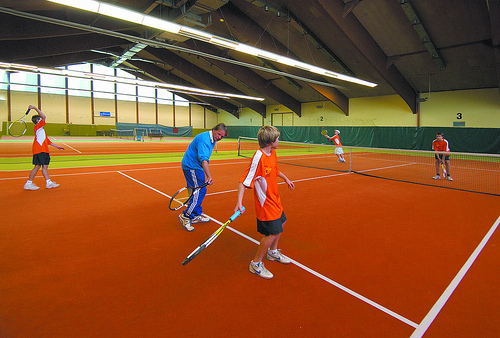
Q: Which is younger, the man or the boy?
A: The boy is younger than the man.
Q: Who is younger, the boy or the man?
A: The boy is younger than the man.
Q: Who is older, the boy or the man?
A: The man is older than the boy.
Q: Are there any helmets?
A: No, there are no helmets.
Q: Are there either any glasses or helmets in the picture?
A: No, there are no helmets or glasses.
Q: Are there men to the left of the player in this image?
A: Yes, there is a man to the left of the player.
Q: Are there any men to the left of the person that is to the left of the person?
A: Yes, there is a man to the left of the player.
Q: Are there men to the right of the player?
A: No, the man is to the left of the player.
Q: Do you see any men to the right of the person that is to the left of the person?
A: No, the man is to the left of the player.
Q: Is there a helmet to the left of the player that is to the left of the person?
A: No, there is a man to the left of the player.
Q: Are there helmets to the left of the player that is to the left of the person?
A: No, there is a man to the left of the player.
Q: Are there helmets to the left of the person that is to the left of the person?
A: No, there is a man to the left of the player.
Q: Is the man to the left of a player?
A: Yes, the man is to the left of a player.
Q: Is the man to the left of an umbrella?
A: No, the man is to the left of a player.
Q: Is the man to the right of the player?
A: No, the man is to the left of the player.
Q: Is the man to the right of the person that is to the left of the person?
A: No, the man is to the left of the player.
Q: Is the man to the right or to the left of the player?
A: The man is to the left of the player.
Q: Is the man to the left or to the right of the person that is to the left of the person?
A: The man is to the left of the player.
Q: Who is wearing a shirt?
A: The man is wearing a shirt.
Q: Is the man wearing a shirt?
A: Yes, the man is wearing a shirt.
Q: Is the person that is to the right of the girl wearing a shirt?
A: Yes, the man is wearing a shirt.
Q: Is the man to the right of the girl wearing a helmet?
A: No, the man is wearing a shirt.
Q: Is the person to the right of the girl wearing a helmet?
A: No, the man is wearing a shirt.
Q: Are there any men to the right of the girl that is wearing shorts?
A: Yes, there is a man to the right of the girl.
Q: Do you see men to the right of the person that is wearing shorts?
A: Yes, there is a man to the right of the girl.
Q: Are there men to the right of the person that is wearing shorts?
A: Yes, there is a man to the right of the girl.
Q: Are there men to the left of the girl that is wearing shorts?
A: No, the man is to the right of the girl.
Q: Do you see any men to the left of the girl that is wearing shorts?
A: No, the man is to the right of the girl.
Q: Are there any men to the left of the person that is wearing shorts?
A: No, the man is to the right of the girl.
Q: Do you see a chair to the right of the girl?
A: No, there is a man to the right of the girl.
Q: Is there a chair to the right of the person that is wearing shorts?
A: No, there is a man to the right of the girl.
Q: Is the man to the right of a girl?
A: Yes, the man is to the right of a girl.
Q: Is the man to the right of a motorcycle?
A: No, the man is to the right of a girl.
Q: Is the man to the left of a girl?
A: No, the man is to the right of a girl.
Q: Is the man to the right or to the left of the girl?
A: The man is to the right of the girl.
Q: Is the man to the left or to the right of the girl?
A: The man is to the right of the girl.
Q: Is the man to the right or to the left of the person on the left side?
A: The man is to the right of the girl.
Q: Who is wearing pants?
A: The man is wearing pants.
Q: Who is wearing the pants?
A: The man is wearing pants.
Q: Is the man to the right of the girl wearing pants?
A: Yes, the man is wearing pants.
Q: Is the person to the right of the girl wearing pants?
A: Yes, the man is wearing pants.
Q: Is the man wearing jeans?
A: No, the man is wearing pants.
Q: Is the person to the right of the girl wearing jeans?
A: No, the man is wearing pants.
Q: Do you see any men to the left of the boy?
A: Yes, there is a man to the left of the boy.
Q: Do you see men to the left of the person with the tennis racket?
A: Yes, there is a man to the left of the boy.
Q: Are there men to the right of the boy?
A: No, the man is to the left of the boy.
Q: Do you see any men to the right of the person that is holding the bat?
A: No, the man is to the left of the boy.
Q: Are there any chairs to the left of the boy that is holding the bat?
A: No, there is a man to the left of the boy.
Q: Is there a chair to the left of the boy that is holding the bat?
A: No, there is a man to the left of the boy.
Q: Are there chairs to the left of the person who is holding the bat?
A: No, there is a man to the left of the boy.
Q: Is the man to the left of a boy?
A: Yes, the man is to the left of a boy.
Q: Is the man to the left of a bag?
A: No, the man is to the left of a boy.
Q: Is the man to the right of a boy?
A: No, the man is to the left of a boy.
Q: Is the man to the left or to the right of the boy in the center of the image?
A: The man is to the left of the boy.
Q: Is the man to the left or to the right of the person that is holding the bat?
A: The man is to the left of the boy.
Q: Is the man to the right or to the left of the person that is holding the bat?
A: The man is to the left of the boy.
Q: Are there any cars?
A: No, there are no cars.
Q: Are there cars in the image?
A: No, there are no cars.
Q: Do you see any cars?
A: No, there are no cars.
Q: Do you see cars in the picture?
A: No, there are no cars.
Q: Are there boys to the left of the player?
A: Yes, there is a boy to the left of the player.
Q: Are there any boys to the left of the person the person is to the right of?
A: Yes, there is a boy to the left of the player.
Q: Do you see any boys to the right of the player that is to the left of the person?
A: No, the boy is to the left of the player.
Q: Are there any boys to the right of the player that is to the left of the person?
A: No, the boy is to the left of the player.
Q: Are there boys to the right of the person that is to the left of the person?
A: No, the boy is to the left of the player.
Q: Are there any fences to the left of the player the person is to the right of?
A: No, there is a boy to the left of the player.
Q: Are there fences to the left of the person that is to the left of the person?
A: No, there is a boy to the left of the player.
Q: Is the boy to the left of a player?
A: Yes, the boy is to the left of a player.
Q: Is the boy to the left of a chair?
A: No, the boy is to the left of a player.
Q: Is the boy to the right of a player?
A: No, the boy is to the left of a player.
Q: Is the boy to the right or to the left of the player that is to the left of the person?
A: The boy is to the left of the player.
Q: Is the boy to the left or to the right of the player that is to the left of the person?
A: The boy is to the left of the player.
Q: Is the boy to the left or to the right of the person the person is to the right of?
A: The boy is to the left of the player.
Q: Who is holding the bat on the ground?
A: The boy is holding the bat.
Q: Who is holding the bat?
A: The boy is holding the bat.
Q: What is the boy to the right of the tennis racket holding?
A: The boy is holding the bat.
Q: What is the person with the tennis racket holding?
A: The boy is holding the bat.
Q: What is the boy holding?
A: The boy is holding the bat.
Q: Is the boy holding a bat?
A: Yes, the boy is holding a bat.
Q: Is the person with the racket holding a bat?
A: Yes, the boy is holding a bat.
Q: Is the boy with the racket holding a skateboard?
A: No, the boy is holding a bat.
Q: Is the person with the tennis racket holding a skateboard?
A: No, the boy is holding a bat.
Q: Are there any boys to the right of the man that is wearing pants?
A: Yes, there is a boy to the right of the man.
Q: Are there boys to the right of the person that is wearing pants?
A: Yes, there is a boy to the right of the man.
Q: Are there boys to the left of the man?
A: No, the boy is to the right of the man.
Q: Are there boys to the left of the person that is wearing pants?
A: No, the boy is to the right of the man.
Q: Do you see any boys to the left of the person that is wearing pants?
A: No, the boy is to the right of the man.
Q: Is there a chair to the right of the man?
A: No, there is a boy to the right of the man.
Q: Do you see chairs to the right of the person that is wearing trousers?
A: No, there is a boy to the right of the man.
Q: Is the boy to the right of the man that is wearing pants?
A: Yes, the boy is to the right of the man.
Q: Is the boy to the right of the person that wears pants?
A: Yes, the boy is to the right of the man.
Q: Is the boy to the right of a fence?
A: No, the boy is to the right of the man.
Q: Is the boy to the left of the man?
A: No, the boy is to the right of the man.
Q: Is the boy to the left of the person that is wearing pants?
A: No, the boy is to the right of the man.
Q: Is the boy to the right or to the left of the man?
A: The boy is to the right of the man.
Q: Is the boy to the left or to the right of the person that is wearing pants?
A: The boy is to the right of the man.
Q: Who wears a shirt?
A: The boy wears a shirt.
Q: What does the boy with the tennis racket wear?
A: The boy wears a shirt.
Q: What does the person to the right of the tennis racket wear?
A: The boy wears a shirt.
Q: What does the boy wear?
A: The boy wears a shirt.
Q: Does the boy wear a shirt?
A: Yes, the boy wears a shirt.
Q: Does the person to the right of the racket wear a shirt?
A: Yes, the boy wears a shirt.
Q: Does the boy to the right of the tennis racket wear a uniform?
A: No, the boy wears a shirt.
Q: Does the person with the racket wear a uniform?
A: No, the boy wears a shirt.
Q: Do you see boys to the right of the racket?
A: Yes, there is a boy to the right of the racket.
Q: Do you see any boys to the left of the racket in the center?
A: No, the boy is to the right of the tennis racket.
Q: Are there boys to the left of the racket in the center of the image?
A: No, the boy is to the right of the tennis racket.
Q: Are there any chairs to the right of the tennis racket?
A: No, there is a boy to the right of the tennis racket.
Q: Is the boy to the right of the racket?
A: Yes, the boy is to the right of the racket.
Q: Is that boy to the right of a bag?
A: No, the boy is to the right of the racket.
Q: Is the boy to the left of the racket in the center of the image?
A: No, the boy is to the right of the tennis racket.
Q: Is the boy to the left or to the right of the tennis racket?
A: The boy is to the right of the tennis racket.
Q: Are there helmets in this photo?
A: No, there are no helmets.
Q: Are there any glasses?
A: No, there are no glasses.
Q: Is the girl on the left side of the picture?
A: Yes, the girl is on the left of the image.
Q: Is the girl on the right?
A: No, the girl is on the left of the image.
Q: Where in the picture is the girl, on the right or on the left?
A: The girl is on the left of the image.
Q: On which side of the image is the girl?
A: The girl is on the left of the image.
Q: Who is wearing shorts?
A: The girl is wearing shorts.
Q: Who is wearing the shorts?
A: The girl is wearing shorts.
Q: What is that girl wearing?
A: The girl is wearing shorts.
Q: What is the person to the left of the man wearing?
A: The girl is wearing shorts.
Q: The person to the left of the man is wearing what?
A: The girl is wearing shorts.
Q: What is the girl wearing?
A: The girl is wearing shorts.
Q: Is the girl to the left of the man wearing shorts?
A: Yes, the girl is wearing shorts.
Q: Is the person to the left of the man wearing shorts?
A: Yes, the girl is wearing shorts.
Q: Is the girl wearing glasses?
A: No, the girl is wearing shorts.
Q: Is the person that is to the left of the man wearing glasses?
A: No, the girl is wearing shorts.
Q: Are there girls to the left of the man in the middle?
A: Yes, there is a girl to the left of the man.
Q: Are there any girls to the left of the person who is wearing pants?
A: Yes, there is a girl to the left of the man.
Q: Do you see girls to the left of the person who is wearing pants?
A: Yes, there is a girl to the left of the man.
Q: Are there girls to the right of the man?
A: No, the girl is to the left of the man.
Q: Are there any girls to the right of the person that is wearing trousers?
A: No, the girl is to the left of the man.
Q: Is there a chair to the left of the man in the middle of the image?
A: No, there is a girl to the left of the man.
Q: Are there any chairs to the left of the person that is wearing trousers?
A: No, there is a girl to the left of the man.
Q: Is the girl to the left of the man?
A: Yes, the girl is to the left of the man.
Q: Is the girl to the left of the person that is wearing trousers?
A: Yes, the girl is to the left of the man.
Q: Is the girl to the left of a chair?
A: No, the girl is to the left of the man.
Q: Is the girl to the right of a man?
A: No, the girl is to the left of a man.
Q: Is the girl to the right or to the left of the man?
A: The girl is to the left of the man.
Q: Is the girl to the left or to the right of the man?
A: The girl is to the left of the man.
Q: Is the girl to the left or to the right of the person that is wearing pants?
A: The girl is to the left of the man.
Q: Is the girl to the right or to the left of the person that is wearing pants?
A: The girl is to the left of the man.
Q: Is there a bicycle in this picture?
A: No, there are no bicycles.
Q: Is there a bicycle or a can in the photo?
A: No, there are no bicycles or cans.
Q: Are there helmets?
A: No, there are no helmets.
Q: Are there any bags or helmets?
A: No, there are no helmets or bags.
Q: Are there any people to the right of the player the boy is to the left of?
A: Yes, there is a person to the right of the player.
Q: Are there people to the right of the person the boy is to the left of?
A: Yes, there is a person to the right of the player.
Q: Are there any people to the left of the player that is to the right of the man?
A: No, the person is to the right of the player.